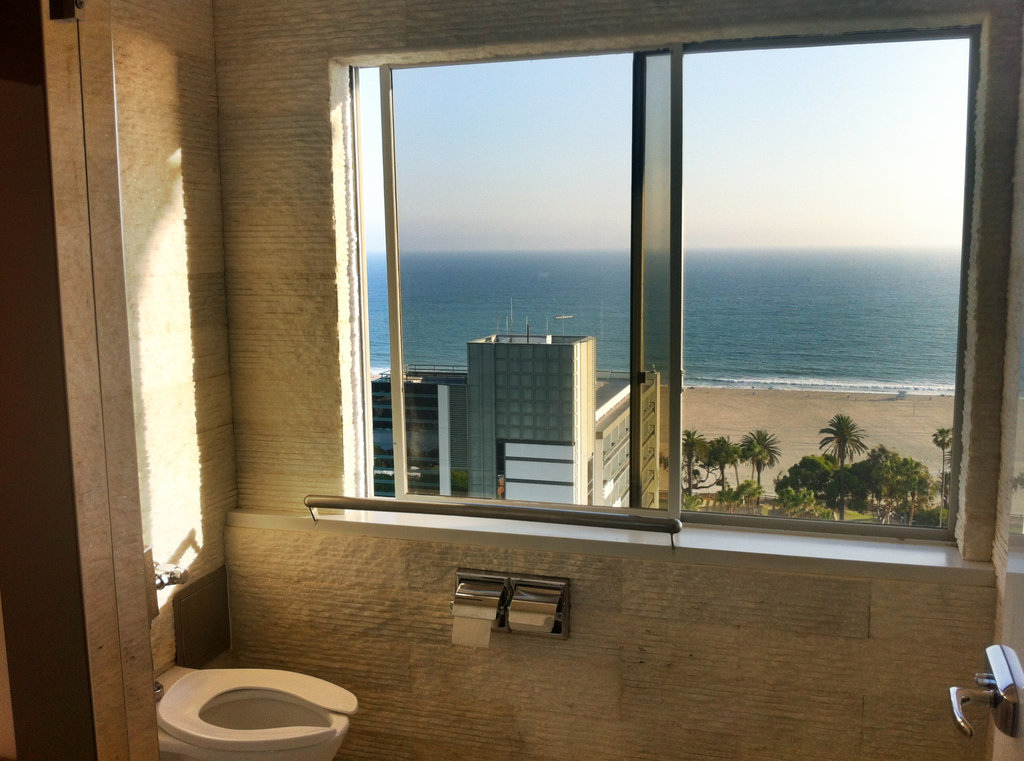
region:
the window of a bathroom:
[321, 37, 935, 587]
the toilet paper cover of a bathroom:
[415, 557, 599, 659]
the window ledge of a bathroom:
[362, 481, 955, 589]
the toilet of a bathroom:
[111, 639, 380, 753]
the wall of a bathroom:
[64, 28, 251, 560]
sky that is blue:
[453, 83, 575, 161]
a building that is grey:
[462, 320, 596, 483]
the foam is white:
[751, 349, 834, 407]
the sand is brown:
[768, 387, 822, 438]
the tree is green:
[804, 450, 874, 499]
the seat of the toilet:
[182, 634, 310, 755]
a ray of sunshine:
[141, 286, 239, 454]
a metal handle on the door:
[890, 646, 1002, 755]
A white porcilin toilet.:
[118, 533, 388, 758]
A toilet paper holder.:
[422, 557, 577, 660]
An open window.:
[315, 40, 992, 568]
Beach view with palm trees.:
[310, 45, 997, 574]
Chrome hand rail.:
[291, 475, 725, 589]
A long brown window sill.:
[334, 454, 965, 592]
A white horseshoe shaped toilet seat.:
[119, 551, 361, 758]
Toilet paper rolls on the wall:
[443, 573, 564, 656]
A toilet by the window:
[156, 667, 354, 759]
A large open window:
[333, 26, 979, 529]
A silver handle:
[943, 648, 1016, 741]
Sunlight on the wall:
[127, 200, 216, 594]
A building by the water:
[367, 329, 668, 517]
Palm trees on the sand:
[672, 418, 955, 542]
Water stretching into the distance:
[364, 226, 956, 394]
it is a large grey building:
[470, 334, 589, 481]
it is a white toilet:
[160, 660, 338, 759]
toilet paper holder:
[452, 579, 563, 641]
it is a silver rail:
[299, 484, 688, 567]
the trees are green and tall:
[697, 427, 925, 525]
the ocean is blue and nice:
[392, 256, 968, 392]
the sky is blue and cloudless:
[416, 59, 942, 253]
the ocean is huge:
[373, 240, 955, 377]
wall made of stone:
[232, 3, 995, 759]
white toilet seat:
[159, 661, 352, 745]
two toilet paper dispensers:
[449, 566, 576, 649]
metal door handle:
[947, 642, 1011, 753]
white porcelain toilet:
[163, 663, 348, 752]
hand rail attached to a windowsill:
[296, 489, 685, 554]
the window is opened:
[334, 59, 407, 508]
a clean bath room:
[21, 6, 1006, 714]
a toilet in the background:
[53, 486, 426, 755]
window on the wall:
[262, 31, 1021, 583]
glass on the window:
[293, 34, 895, 661]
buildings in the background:
[362, 247, 811, 753]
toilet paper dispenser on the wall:
[445, 566, 578, 656]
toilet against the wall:
[158, 655, 361, 755]